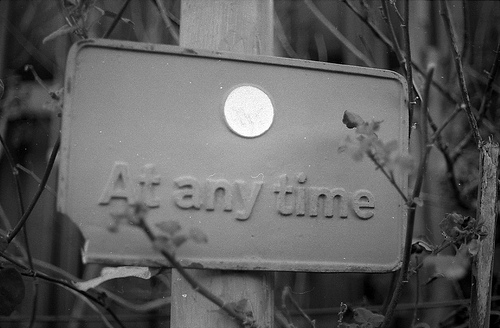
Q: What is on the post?
A: Sign.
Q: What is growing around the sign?
A: Bushes.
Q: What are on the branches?
A: Leaves.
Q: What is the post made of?
A: Wood.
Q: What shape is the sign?
A: Rectangle.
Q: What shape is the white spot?
A: Circle.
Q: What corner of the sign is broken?
A: Lower left.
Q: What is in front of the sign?
A: Branches.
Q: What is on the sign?
A: Writing.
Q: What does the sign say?
A: At any time.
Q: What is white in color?
A: The circle.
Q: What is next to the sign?
A: Branches.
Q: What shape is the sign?
A: Square.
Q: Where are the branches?
A: Next to sign.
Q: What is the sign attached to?
A: Pole.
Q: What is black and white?
A: The picture.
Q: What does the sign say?
A: At any time.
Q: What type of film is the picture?
A: Black and white.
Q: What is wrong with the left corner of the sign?
A: A piece is missing.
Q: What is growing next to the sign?
A: Plants.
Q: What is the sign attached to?
A: A post.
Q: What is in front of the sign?
A: Branches.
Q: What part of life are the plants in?
A: Death.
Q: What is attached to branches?
A: Leaves.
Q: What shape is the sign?
A: Rectangle.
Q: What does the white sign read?
A: At any time.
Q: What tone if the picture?
A: Black and white.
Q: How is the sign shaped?
A: Rectangularly.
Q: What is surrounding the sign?
A: Trees.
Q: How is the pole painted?
A: White.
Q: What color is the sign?
A: Gray.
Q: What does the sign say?
A: At any time.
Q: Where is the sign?
A: On a post.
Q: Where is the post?
A: Behind the sign.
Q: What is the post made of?
A: Wood.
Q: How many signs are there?
A: One.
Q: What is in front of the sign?
A: Branches.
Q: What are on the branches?
A: Leaves.